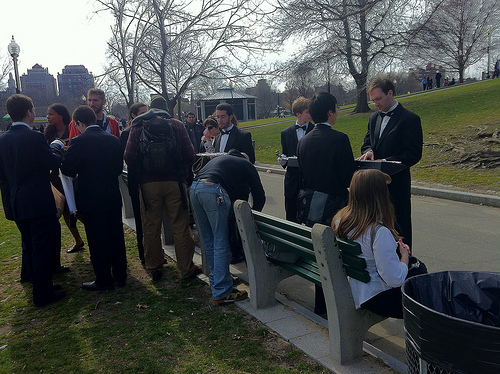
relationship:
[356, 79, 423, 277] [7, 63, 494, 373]
man in park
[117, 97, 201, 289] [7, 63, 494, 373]
man in park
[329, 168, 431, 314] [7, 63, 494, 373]
woman in park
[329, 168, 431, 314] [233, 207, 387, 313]
woman on bench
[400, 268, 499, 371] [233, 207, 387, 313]
trash can next to bench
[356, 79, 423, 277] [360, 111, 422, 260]
man in suit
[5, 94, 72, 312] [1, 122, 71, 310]
man in suit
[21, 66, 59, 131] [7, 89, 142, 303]
buiding behind people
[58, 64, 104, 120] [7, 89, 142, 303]
buiding behind people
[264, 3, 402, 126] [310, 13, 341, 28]
tree has no leaves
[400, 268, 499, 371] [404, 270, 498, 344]
trash can has bag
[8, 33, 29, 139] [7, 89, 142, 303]
light behind people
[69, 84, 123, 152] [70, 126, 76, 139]
man wearing red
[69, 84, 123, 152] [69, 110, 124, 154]
man wearing jacket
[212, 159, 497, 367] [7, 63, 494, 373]
road in park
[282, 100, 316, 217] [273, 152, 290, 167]
boy holding bell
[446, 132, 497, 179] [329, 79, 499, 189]
roots on ground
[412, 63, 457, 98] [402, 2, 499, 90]
people under tree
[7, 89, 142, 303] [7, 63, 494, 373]
people at park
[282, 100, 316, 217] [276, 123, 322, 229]
boy in suit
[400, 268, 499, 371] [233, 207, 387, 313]
trash can beside bench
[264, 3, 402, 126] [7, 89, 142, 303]
tree behind people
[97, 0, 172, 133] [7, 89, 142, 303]
tree behind people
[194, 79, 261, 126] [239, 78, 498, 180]
buiding on grass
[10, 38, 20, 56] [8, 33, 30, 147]
light on pole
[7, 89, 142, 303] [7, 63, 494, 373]
people in park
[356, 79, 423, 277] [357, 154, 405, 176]
man touches tray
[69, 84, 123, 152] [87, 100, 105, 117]
man with beard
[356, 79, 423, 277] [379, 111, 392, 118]
man wearing tie